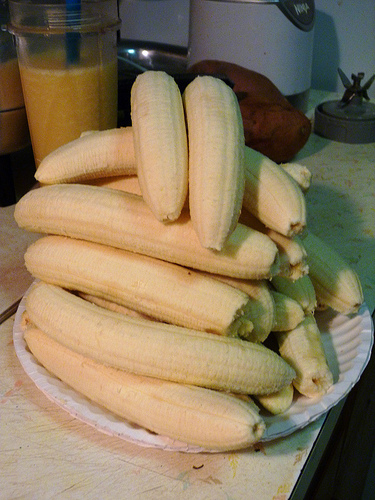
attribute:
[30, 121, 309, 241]
banana — peeled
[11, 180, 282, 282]
banana — peeled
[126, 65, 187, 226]
banana — peeled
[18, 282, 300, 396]
banana — peeled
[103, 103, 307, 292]
banana — peeled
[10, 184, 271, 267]
banana — peeled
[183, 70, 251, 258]
banana — peeled